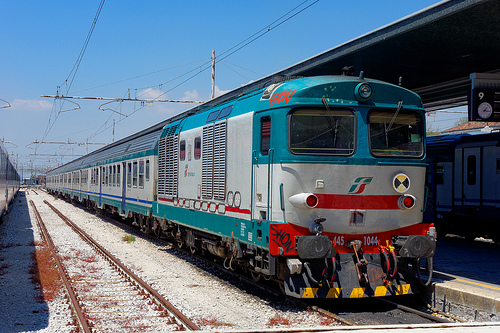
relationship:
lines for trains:
[66, 45, 132, 124] [172, 105, 413, 290]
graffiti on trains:
[268, 226, 302, 261] [172, 105, 413, 290]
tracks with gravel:
[38, 255, 153, 332] [46, 208, 72, 234]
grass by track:
[111, 227, 161, 262] [326, 299, 357, 325]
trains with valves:
[172, 105, 413, 290] [382, 175, 413, 194]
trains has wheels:
[172, 105, 413, 290] [244, 242, 270, 298]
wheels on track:
[244, 242, 270, 298] [326, 299, 357, 325]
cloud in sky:
[16, 88, 52, 123] [216, 26, 227, 29]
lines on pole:
[66, 45, 132, 124] [213, 39, 215, 91]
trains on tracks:
[172, 105, 413, 290] [38, 255, 153, 332]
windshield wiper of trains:
[312, 99, 364, 151] [172, 105, 413, 290]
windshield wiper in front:
[312, 99, 364, 151] [372, 101, 424, 157]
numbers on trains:
[327, 229, 392, 255] [172, 105, 413, 290]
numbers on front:
[327, 229, 392, 255] [372, 101, 424, 157]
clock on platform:
[456, 65, 495, 134] [467, 266, 498, 321]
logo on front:
[345, 171, 376, 206] [372, 101, 424, 157]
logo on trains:
[345, 171, 376, 206] [172, 105, 413, 290]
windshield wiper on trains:
[312, 99, 364, 151] [172, 105, 413, 290]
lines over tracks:
[66, 45, 132, 124] [38, 255, 153, 332]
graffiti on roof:
[268, 226, 302, 261] [251, 72, 292, 123]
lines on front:
[66, 45, 132, 124] [372, 101, 424, 157]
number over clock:
[474, 84, 491, 98] [456, 65, 495, 134]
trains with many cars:
[172, 105, 413, 290] [44, 163, 165, 231]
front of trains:
[372, 101, 424, 157] [172, 105, 413, 290]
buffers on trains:
[294, 272, 442, 298] [172, 105, 413, 290]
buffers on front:
[294, 272, 442, 298] [372, 101, 424, 157]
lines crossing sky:
[66, 45, 132, 124] [216, 26, 227, 29]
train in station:
[424, 133, 498, 233] [394, 26, 474, 79]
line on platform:
[437, 262, 493, 316] [467, 266, 498, 321]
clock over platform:
[456, 65, 495, 134] [467, 266, 498, 321]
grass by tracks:
[111, 227, 161, 262] [38, 255, 153, 332]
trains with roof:
[172, 105, 413, 290] [251, 72, 292, 123]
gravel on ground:
[46, 208, 72, 234] [3, 299, 40, 322]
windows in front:
[282, 105, 435, 172] [372, 101, 424, 157]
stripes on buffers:
[306, 282, 314, 289] [294, 272, 442, 298]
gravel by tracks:
[46, 208, 72, 234] [38, 255, 153, 332]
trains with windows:
[172, 105, 413, 290] [282, 105, 435, 172]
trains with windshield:
[172, 105, 413, 290] [282, 105, 435, 172]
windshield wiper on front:
[312, 99, 364, 151] [372, 101, 424, 157]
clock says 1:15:
[456, 65, 495, 134] [483, 108, 487, 109]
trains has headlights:
[172, 105, 413, 290] [290, 175, 435, 225]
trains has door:
[172, 105, 413, 290] [118, 160, 130, 226]